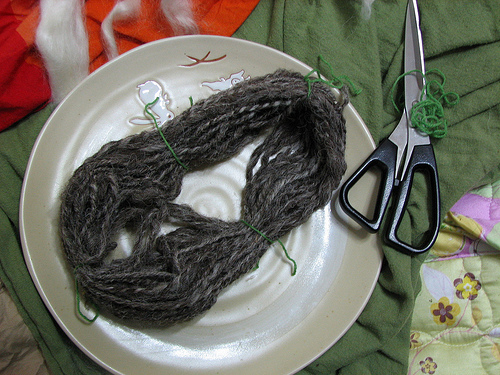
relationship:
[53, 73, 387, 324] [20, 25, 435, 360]
yarn on plate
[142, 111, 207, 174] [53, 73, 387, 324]
thread on yarn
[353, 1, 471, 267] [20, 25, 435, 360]
scissors near plate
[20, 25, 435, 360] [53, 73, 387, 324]
plate underneath yarn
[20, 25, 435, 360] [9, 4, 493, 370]
plate on fabric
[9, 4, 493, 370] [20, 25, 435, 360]
fabric under plate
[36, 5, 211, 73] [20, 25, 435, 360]
hair near plate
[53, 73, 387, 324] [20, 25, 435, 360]
yarn on top plate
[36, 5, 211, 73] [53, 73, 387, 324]
hair near yarn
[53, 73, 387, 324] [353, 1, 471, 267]
yarn near scissors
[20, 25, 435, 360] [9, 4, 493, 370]
plate above fabric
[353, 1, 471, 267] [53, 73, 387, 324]
scissors near yarn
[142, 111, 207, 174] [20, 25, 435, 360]
thread on plate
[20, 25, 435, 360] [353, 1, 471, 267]
plate near scissors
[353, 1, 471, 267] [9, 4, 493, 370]
scissors on top of fabric